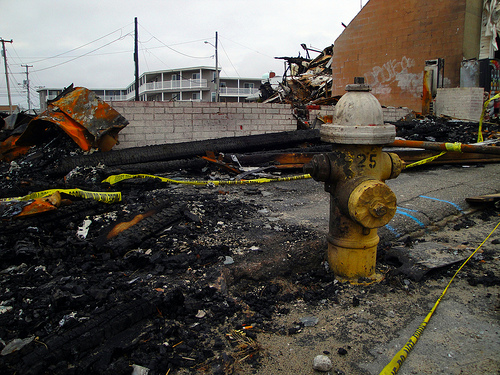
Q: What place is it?
A: It is a street.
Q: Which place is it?
A: It is a street.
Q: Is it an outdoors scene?
A: Yes, it is outdoors.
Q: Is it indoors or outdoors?
A: It is outdoors.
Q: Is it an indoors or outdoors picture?
A: It is outdoors.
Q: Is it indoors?
A: No, it is outdoors.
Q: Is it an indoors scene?
A: No, it is outdoors.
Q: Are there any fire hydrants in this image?
A: Yes, there is a fire hydrant.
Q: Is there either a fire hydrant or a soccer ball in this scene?
A: Yes, there is a fire hydrant.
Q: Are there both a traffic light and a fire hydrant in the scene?
A: No, there is a fire hydrant but no traffic lights.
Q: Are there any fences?
A: No, there are no fences.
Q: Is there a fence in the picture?
A: No, there are no fences.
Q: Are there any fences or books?
A: No, there are no fences or books.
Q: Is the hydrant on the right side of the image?
A: Yes, the hydrant is on the right of the image.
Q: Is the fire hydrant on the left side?
A: No, the fire hydrant is on the right of the image.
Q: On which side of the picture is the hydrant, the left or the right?
A: The hydrant is on the right of the image.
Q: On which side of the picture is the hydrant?
A: The hydrant is on the right of the image.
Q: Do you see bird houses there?
A: No, there are no bird houses.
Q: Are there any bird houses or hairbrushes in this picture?
A: No, there are no bird houses or hairbrushes.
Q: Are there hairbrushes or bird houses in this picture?
A: No, there are no bird houses or hairbrushes.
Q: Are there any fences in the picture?
A: No, there are no fences.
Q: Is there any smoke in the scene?
A: Yes, there is smoke.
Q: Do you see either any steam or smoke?
A: Yes, there is smoke.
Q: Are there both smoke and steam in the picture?
A: No, there is smoke but no steam.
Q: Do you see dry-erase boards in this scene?
A: No, there are no dry-erase boards.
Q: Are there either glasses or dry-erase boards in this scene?
A: No, there are no dry-erase boards or glasses.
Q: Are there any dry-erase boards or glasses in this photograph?
A: No, there are no dry-erase boards or glasses.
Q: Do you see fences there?
A: No, there are no fences.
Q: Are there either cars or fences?
A: No, there are no fences or cars.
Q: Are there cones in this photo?
A: No, there are no cones.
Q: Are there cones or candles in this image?
A: No, there are no cones or candles.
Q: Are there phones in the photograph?
A: Yes, there is a phone.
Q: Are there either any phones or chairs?
A: Yes, there is a phone.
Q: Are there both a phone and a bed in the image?
A: No, there is a phone but no beds.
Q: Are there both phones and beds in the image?
A: No, there is a phone but no beds.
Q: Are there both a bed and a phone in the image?
A: No, there is a phone but no beds.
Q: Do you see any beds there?
A: No, there are no beds.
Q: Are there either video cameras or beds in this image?
A: No, there are no beds or video cameras.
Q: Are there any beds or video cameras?
A: No, there are no beds or video cameras.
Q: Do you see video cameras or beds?
A: No, there are no beds or video cameras.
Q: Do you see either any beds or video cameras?
A: No, there are no beds or video cameras.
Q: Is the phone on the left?
A: Yes, the phone is on the left of the image.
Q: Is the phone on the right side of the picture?
A: No, the phone is on the left of the image.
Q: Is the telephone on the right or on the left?
A: The telephone is on the left of the image.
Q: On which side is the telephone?
A: The telephone is on the left of the image.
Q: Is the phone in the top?
A: Yes, the phone is in the top of the image.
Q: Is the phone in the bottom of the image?
A: No, the phone is in the top of the image.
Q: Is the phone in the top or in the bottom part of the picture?
A: The phone is in the top of the image.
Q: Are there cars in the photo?
A: No, there are no cars.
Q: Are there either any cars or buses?
A: No, there are no cars or buses.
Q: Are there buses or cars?
A: No, there are no cars or buses.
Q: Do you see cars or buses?
A: No, there are no cars or buses.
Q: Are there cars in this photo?
A: No, there are no cars.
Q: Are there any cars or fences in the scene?
A: No, there are no cars or fences.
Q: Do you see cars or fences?
A: No, there are no cars or fences.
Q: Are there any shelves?
A: No, there are no shelves.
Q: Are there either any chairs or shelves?
A: No, there are no shelves or chairs.